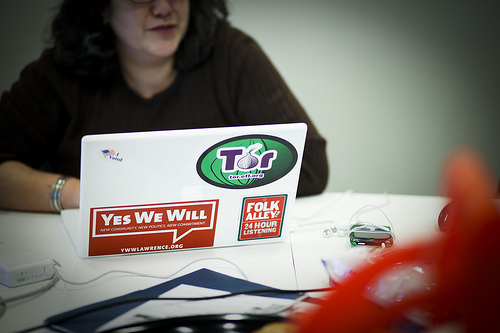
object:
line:
[238, 197, 245, 241]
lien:
[347, 204, 394, 223]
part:
[350, 231, 373, 246]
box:
[349, 223, 393, 247]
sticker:
[196, 134, 298, 190]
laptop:
[61, 121, 310, 259]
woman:
[0, 0, 327, 212]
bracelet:
[49, 173, 70, 212]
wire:
[0, 258, 332, 333]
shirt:
[0, 19, 328, 198]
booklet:
[43, 266, 310, 332]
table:
[0, 193, 500, 333]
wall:
[328, 1, 500, 195]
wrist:
[67, 175, 79, 209]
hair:
[175, 0, 227, 76]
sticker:
[100, 149, 123, 162]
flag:
[101, 149, 116, 159]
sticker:
[88, 198, 220, 256]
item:
[290, 146, 498, 333]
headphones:
[347, 222, 391, 249]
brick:
[0, 248, 55, 288]